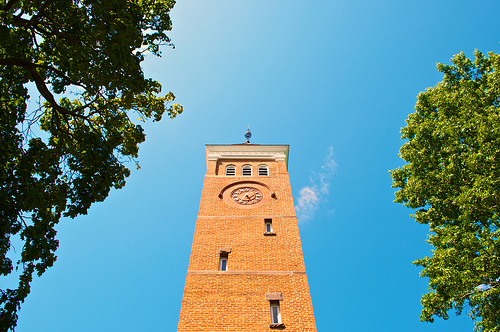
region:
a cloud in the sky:
[291, 178, 328, 213]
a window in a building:
[262, 287, 287, 330]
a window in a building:
[212, 243, 236, 273]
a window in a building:
[260, 214, 278, 239]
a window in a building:
[222, 160, 239, 177]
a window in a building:
[237, 157, 256, 181]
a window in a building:
[253, 158, 274, 180]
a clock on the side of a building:
[226, 182, 265, 204]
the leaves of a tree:
[435, 138, 492, 228]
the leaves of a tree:
[72, 125, 110, 191]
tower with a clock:
[178, 118, 325, 327]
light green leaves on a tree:
[391, 51, 495, 325]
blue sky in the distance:
[326, 210, 391, 294]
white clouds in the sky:
[294, 177, 317, 227]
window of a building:
[263, 288, 293, 325]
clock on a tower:
[221, 179, 268, 209]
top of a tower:
[240, 127, 258, 149]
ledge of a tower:
[233, 265, 298, 280]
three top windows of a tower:
[220, 153, 277, 184]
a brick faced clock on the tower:
[231, 183, 261, 203]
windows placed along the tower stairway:
[213, 215, 288, 326]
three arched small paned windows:
[224, 161, 274, 176]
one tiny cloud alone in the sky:
[295, 143, 339, 225]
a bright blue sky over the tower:
[0, 1, 497, 331]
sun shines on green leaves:
[392, 46, 494, 331]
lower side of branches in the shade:
[0, 3, 180, 331]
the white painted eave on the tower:
[201, 138, 290, 161]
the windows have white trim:
[269, 291, 285, 328]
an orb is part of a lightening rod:
[243, 121, 253, 148]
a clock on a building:
[221, 167, 301, 217]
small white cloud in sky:
[288, 136, 359, 250]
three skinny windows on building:
[209, 217, 298, 331]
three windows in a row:
[218, 145, 280, 184]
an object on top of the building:
[241, 120, 261, 148]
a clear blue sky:
[2, 10, 494, 330]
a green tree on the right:
[359, 68, 494, 323]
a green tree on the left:
[3, 6, 155, 330]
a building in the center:
[161, 116, 341, 326]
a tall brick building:
[180, 134, 353, 329]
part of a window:
[277, 300, 281, 308]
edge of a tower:
[301, 280, 313, 317]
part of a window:
[273, 312, 284, 327]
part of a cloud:
[302, 168, 330, 228]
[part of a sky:
[335, 265, 352, 305]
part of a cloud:
[304, 194, 314, 221]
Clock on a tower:
[218, 172, 279, 210]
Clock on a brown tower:
[214, 175, 280, 213]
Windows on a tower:
[211, 213, 293, 321]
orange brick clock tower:
[186, 127, 321, 331]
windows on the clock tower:
[210, 160, 285, 329]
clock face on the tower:
[229, 180, 261, 203]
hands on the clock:
[242, 190, 255, 203]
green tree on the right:
[387, 35, 499, 320]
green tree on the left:
[4, 7, 164, 331]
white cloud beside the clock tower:
[293, 140, 335, 213]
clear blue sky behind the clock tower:
[9, 3, 496, 330]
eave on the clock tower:
[205, 142, 287, 161]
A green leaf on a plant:
[429, 139, 434, 142]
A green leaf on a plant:
[451, 114, 456, 117]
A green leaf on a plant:
[460, 111, 463, 113]